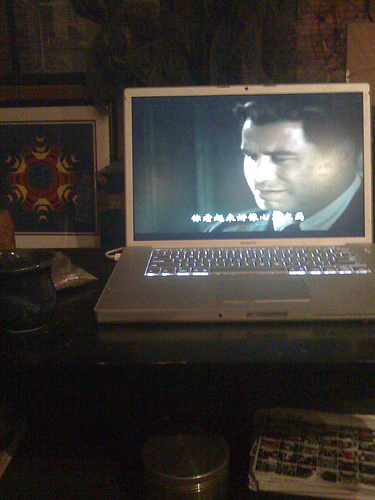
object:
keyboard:
[142, 244, 370, 276]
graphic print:
[0, 82, 116, 251]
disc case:
[137, 429, 232, 497]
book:
[246, 406, 375, 498]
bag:
[45, 250, 102, 290]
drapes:
[91, 3, 299, 118]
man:
[202, 97, 365, 232]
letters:
[189, 209, 201, 221]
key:
[146, 265, 163, 274]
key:
[208, 265, 287, 276]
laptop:
[93, 81, 375, 366]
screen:
[130, 94, 364, 239]